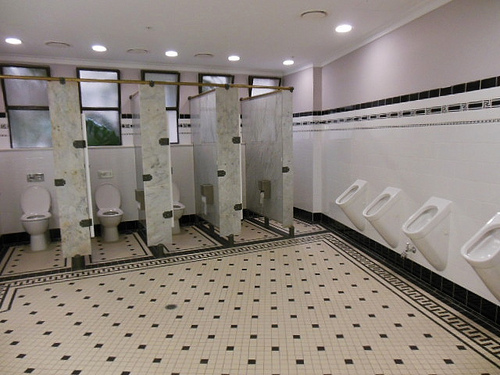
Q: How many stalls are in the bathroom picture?
A: 4.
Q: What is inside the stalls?
A: Toilets.